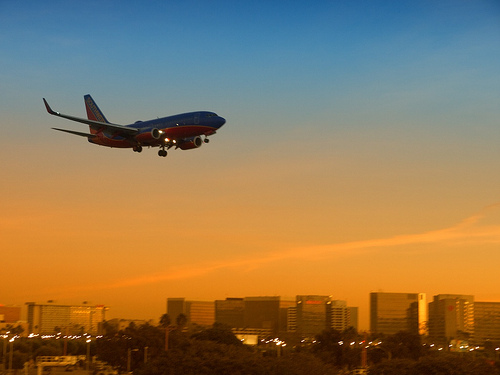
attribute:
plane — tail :
[86, 97, 223, 151]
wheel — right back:
[160, 134, 211, 169]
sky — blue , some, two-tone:
[1, 1, 498, 328]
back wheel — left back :
[131, 141, 146, 154]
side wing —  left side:
[51, 125, 95, 138]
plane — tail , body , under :
[40, 93, 227, 158]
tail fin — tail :
[43, 88, 112, 143]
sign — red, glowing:
[305, 298, 323, 306]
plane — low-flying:
[30, 75, 235, 176]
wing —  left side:
[39, 96, 139, 136]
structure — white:
[36, 354, 90, 371]